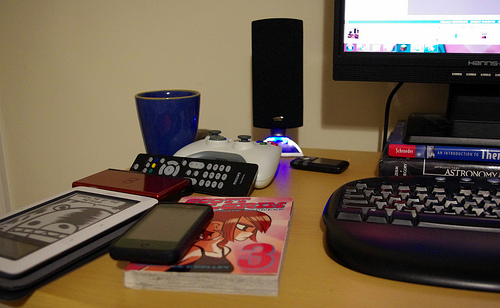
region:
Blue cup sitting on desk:
[131, 77, 208, 162]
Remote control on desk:
[133, 148, 260, 203]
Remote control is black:
[124, 149, 269, 196]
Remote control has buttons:
[151, 155, 245, 190]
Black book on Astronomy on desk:
[365, 155, 497, 182]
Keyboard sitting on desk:
[326, 172, 498, 294]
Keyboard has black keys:
[329, 174, 494, 295]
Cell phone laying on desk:
[289, 150, 354, 180]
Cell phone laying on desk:
[117, 195, 202, 272]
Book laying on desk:
[179, 187, 315, 306]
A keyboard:
[380, 179, 400, 254]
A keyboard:
[354, 190, 405, 260]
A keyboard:
[361, 181, 388, 241]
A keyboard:
[363, 189, 388, 254]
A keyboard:
[362, 178, 403, 302]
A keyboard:
[397, 177, 442, 276]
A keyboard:
[345, 218, 398, 297]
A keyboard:
[377, 178, 437, 257]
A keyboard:
[363, 174, 430, 297]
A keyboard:
[399, 194, 450, 304]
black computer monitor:
[330, 0, 497, 87]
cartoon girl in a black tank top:
[180, 207, 272, 277]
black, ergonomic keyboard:
[317, 170, 499, 287]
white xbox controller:
[172, 126, 283, 184]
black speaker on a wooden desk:
[246, 16, 308, 158]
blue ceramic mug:
[133, 87, 201, 155]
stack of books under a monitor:
[375, 116, 499, 175]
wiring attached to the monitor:
[372, 78, 414, 155]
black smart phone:
[109, 199, 214, 263]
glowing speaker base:
[257, 130, 304, 160]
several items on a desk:
[21, 0, 493, 305]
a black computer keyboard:
[315, 170, 495, 285]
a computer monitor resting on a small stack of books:
[331, 2, 497, 177]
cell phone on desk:
[288, 148, 358, 183]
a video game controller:
[171, 128, 282, 186]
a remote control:
[126, 146, 259, 197]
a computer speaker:
[245, 15, 316, 156]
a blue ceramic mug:
[130, 88, 204, 160]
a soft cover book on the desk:
[127, 184, 309, 304]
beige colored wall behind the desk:
[5, 2, 437, 230]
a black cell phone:
[120, 192, 208, 272]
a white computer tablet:
[0, 185, 145, 280]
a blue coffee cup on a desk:
[115, 80, 205, 145]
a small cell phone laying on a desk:
[285, 150, 345, 175]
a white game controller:
[170, 135, 290, 176]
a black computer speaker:
[225, 25, 320, 136]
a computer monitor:
[307, 10, 490, 93]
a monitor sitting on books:
[375, 47, 495, 179]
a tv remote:
[111, 149, 276, 205]